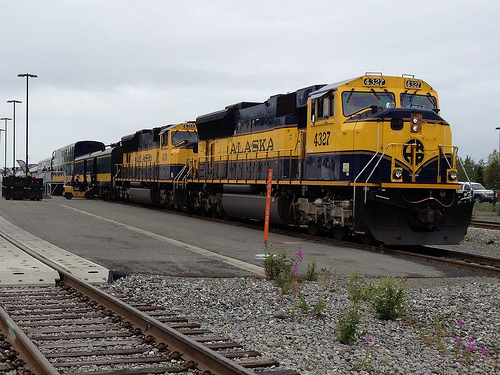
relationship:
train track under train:
[93, 198, 500, 277] [0, 72, 476, 246]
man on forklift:
[74, 172, 86, 189] [62, 165, 98, 200]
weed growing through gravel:
[333, 304, 368, 347] [0, 227, 500, 374]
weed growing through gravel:
[372, 280, 407, 322] [0, 227, 500, 374]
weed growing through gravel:
[258, 242, 303, 297] [0, 227, 500, 374]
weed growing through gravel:
[313, 298, 326, 315] [0, 227, 500, 374]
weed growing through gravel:
[346, 274, 376, 306] [0, 227, 500, 374]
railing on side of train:
[113, 150, 304, 185] [0, 72, 476, 246]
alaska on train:
[230, 138, 274, 154] [0, 72, 476, 246]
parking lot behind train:
[459, 181, 500, 208] [0, 72, 476, 246]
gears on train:
[102, 185, 354, 240] [0, 72, 476, 246]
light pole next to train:
[18, 73, 37, 176] [0, 72, 476, 246]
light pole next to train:
[7, 101, 22, 175] [0, 72, 476, 246]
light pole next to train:
[0, 118, 13, 177] [0, 72, 476, 246]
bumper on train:
[363, 198, 476, 245] [0, 72, 476, 246]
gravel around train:
[0, 227, 500, 374] [0, 72, 476, 246]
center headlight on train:
[412, 124, 420, 132] [0, 72, 476, 246]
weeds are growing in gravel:
[263, 239, 489, 366] [0, 227, 500, 374]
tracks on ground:
[0, 195, 499, 374] [0, 195, 499, 374]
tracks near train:
[0, 195, 499, 374] [0, 72, 476, 246]